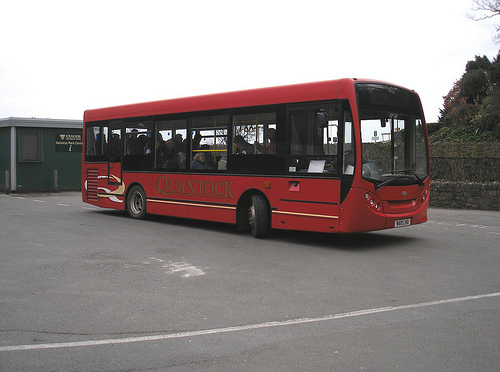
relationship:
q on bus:
[156, 175, 169, 198] [82, 79, 429, 236]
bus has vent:
[82, 79, 429, 236] [86, 168, 100, 201]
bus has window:
[82, 79, 429, 236] [187, 114, 229, 174]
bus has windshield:
[82, 79, 429, 236] [355, 84, 430, 185]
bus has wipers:
[82, 79, 429, 236] [375, 171, 423, 190]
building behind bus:
[0, 117, 84, 194] [82, 79, 429, 236]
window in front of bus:
[355, 84, 430, 185] [82, 79, 429, 236]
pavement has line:
[0, 191, 499, 372] [1, 291, 499, 354]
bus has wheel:
[82, 79, 429, 236] [124, 183, 148, 220]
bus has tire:
[82, 79, 429, 236] [124, 183, 148, 220]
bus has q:
[82, 79, 429, 236] [156, 175, 169, 198]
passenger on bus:
[189, 150, 214, 171] [82, 79, 429, 236]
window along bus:
[187, 114, 229, 174] [82, 79, 429, 236]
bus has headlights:
[82, 79, 429, 236] [363, 192, 379, 209]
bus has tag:
[82, 79, 429, 236] [393, 219, 412, 229]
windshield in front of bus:
[355, 84, 430, 185] [82, 79, 429, 236]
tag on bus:
[393, 219, 412, 229] [82, 79, 429, 236]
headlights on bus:
[363, 192, 379, 209] [82, 79, 429, 236]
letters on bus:
[157, 175, 235, 199] [82, 79, 429, 236]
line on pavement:
[1, 291, 499, 354] [0, 191, 499, 372]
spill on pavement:
[148, 253, 210, 279] [0, 191, 499, 372]